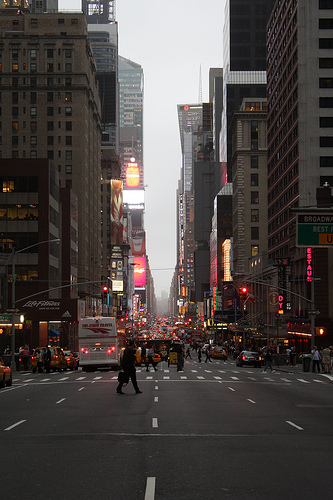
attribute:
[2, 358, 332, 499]
lines — white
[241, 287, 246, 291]
signal — red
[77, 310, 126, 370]
bus — White , red 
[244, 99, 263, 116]
window — three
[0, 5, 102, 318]
building — tall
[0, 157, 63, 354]
building — tall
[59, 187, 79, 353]
building — tall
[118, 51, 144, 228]
building — tall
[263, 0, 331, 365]
building — tall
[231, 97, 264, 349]
building — tall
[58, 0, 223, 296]
sky — grey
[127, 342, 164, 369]
taxi cab — yellow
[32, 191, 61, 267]
building — large, multi level floor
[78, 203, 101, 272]
building — multi level floor, large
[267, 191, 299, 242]
building — large, multi level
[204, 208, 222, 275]
building — multi level, large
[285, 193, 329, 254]
sign — green, white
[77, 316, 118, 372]
bus — red , white 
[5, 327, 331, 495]
roadway — four lane